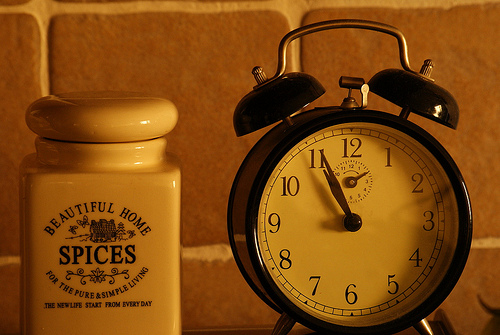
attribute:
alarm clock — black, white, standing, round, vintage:
[228, 19, 474, 334]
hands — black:
[318, 147, 369, 232]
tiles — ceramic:
[0, 1, 500, 334]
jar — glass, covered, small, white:
[18, 136, 182, 334]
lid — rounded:
[25, 91, 179, 143]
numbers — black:
[269, 138, 436, 305]